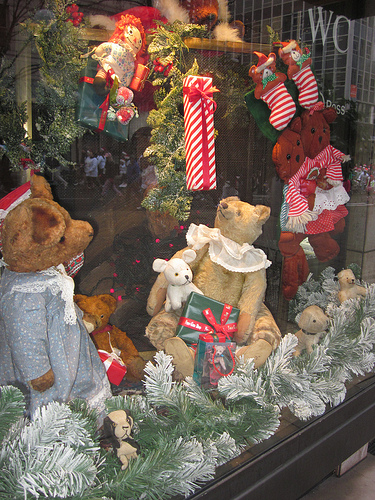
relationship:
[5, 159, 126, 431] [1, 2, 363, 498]
bear in window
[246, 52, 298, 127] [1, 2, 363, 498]
bear in window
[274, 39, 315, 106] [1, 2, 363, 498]
bear in window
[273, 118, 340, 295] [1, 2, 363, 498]
bear in window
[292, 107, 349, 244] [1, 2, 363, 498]
bear in window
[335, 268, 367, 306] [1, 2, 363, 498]
bear in window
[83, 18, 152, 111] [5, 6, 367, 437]
doll in window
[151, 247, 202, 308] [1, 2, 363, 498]
dog in window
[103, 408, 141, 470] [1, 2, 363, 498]
black dog in window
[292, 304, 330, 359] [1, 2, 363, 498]
dog in window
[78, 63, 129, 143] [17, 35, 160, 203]
present in window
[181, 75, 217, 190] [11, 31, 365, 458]
christmas garland in window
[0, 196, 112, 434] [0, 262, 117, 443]
bear with dress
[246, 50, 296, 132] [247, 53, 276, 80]
stocking has a head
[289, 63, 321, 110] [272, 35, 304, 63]
stocking has a head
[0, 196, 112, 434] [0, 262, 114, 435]
bear wearing dress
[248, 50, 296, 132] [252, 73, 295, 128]
bear in stocking